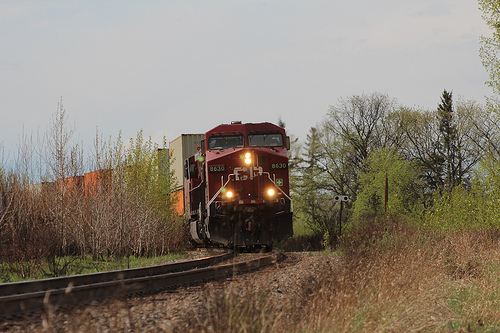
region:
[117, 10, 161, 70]
part of a cloud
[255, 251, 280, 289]
part of a ground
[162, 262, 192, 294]
dge of a rail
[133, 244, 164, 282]
part of a rail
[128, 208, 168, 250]
part fo a plant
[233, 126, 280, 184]
part of a train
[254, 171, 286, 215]
part of a train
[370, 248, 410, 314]
part of a plant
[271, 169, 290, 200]
edge of a train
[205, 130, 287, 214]
headlights of a train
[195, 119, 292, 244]
front of a train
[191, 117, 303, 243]
front of the engine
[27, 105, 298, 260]
train with cargo on it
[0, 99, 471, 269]
train in a rural area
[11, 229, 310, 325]
one set of railroad tracks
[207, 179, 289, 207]
the lower headlights of the engine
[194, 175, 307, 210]
the lower headlights of the train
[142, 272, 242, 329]
gravel on railroad bed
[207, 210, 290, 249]
cattle guard on the engine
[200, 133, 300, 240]
the train lights are on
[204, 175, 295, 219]
the headlights are on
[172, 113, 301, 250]
the conductors car is red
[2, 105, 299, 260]
the train is tall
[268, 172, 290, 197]
a green sign on the front of train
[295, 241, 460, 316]
the grass is dying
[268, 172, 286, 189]
the sign is a plus shape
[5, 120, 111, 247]
the trees are bare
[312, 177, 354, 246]
a traffic light to the right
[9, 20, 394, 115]
the sky is overcast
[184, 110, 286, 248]
train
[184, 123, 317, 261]
cargo train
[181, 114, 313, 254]
red cargo train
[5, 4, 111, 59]
white clouds in light blue sky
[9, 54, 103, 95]
white clouds in light blue sky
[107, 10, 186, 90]
white clouds in light blue sky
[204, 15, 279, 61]
white clouds in light blue sky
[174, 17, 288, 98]
white clouds in light blue sky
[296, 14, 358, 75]
white clouds in light blue sky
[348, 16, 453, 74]
white clouds in light blue sky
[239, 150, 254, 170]
top headlights on train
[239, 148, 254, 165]
to headlights are on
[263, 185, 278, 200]
lef headlight on train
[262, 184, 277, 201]
left headlight is on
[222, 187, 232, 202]
right headlight on train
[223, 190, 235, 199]
right headlight on train is on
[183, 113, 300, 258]
locomotive on train is maroon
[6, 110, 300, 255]
train is riding on tracks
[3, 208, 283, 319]
tracks is holding train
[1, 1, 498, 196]
sky is clear but gray